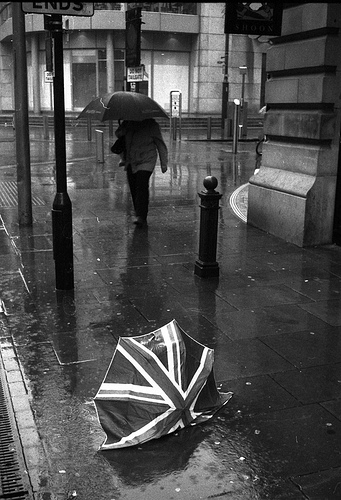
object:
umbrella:
[95, 324, 234, 458]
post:
[194, 174, 223, 282]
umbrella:
[76, 89, 174, 122]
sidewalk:
[0, 125, 338, 497]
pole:
[47, 14, 76, 291]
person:
[109, 92, 168, 230]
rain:
[36, 385, 89, 456]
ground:
[0, 252, 340, 499]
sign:
[19, 1, 93, 18]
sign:
[127, 63, 145, 83]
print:
[93, 318, 235, 451]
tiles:
[52, 325, 117, 362]